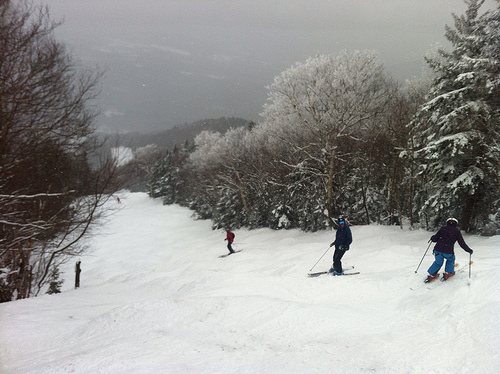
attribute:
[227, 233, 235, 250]
snow suit — red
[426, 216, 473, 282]
people — three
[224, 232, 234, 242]
snow suit — red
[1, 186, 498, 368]
snow — cold, white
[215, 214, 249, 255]
person — one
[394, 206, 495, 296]
person — one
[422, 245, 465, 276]
ski pants — light blue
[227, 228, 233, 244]
coat — red 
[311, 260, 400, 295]
feet — human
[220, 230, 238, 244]
red snowsuit — snow, one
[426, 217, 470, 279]
skier — one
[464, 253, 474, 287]
pole — ski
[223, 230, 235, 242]
jacket — red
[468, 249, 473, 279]
ski pole — one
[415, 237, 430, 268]
ski pole — one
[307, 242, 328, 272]
ski pole — one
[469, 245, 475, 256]
hand — human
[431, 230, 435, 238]
hand — human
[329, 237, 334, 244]
hand — human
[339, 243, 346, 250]
hand — human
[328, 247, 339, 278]
ski pole — one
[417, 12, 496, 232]
tree — snow covered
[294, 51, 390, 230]
tree — snow covered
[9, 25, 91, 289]
tree — snow covered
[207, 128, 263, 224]
tree — snow covered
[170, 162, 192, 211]
tree — snow covered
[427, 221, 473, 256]
jacket — dark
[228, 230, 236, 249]
snowsuit — red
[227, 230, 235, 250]
snowsuit — red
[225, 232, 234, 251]
snow suit — red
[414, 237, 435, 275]
pole — ski